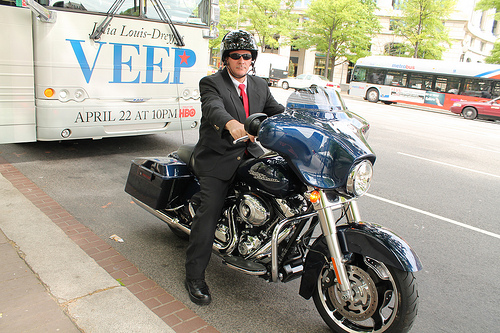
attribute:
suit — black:
[181, 69, 288, 277]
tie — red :
[234, 79, 259, 111]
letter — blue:
[108, 39, 140, 87]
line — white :
[394, 144, 479, 175]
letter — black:
[73, 110, 84, 125]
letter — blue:
[138, 39, 173, 90]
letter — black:
[67, 33, 109, 86]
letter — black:
[84, 110, 93, 123]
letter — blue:
[62, 33, 111, 92]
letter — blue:
[107, 40, 139, 96]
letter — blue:
[166, 43, 196, 88]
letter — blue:
[139, 44, 175, 91]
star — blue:
[172, 45, 204, 64]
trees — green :
[207, 0, 498, 71]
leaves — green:
[279, 2, 400, 91]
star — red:
[170, 50, 193, 73]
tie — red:
[224, 68, 262, 126]